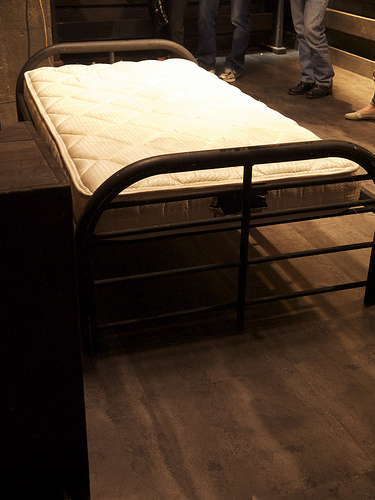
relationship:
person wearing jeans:
[186, 1, 255, 86] [195, 1, 252, 64]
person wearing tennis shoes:
[186, 1, 255, 86] [204, 61, 239, 83]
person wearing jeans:
[283, 4, 336, 89] [288, 2, 335, 81]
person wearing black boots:
[283, 4, 336, 89] [288, 77, 329, 86]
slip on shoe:
[355, 112, 363, 122] [342, 109, 374, 120]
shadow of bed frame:
[64, 209, 320, 368] [17, 31, 374, 345]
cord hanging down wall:
[37, 4, 57, 64] [0, 5, 50, 116]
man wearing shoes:
[283, 4, 336, 89] [285, 76, 334, 104]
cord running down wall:
[37, 4, 57, 64] [0, 5, 50, 116]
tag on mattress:
[211, 188, 266, 218] [19, 54, 373, 230]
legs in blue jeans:
[186, 1, 255, 86] [195, 1, 252, 64]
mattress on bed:
[19, 54, 373, 230] [17, 31, 374, 345]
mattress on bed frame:
[19, 54, 373, 230] [17, 31, 374, 345]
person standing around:
[286, 1, 335, 100] [51, 4, 374, 297]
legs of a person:
[195, 1, 252, 64] [186, 1, 255, 86]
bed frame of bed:
[17, 31, 374, 345] [19, 54, 373, 230]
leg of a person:
[191, 5, 220, 67] [186, 1, 255, 86]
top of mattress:
[22, 58, 350, 193] [19, 54, 373, 230]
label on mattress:
[211, 188, 266, 218] [19, 54, 373, 230]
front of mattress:
[105, 169, 364, 238] [19, 54, 373, 230]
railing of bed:
[74, 143, 374, 319] [17, 31, 374, 345]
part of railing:
[10, 44, 193, 111] [74, 143, 374, 319]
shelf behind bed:
[56, 2, 170, 55] [17, 31, 374, 345]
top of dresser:
[2, 121, 65, 195] [3, 119, 94, 500]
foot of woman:
[341, 105, 375, 124] [341, 75, 375, 122]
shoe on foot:
[342, 109, 374, 120] [341, 105, 375, 124]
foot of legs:
[342, 104, 375, 123] [147, 2, 374, 119]